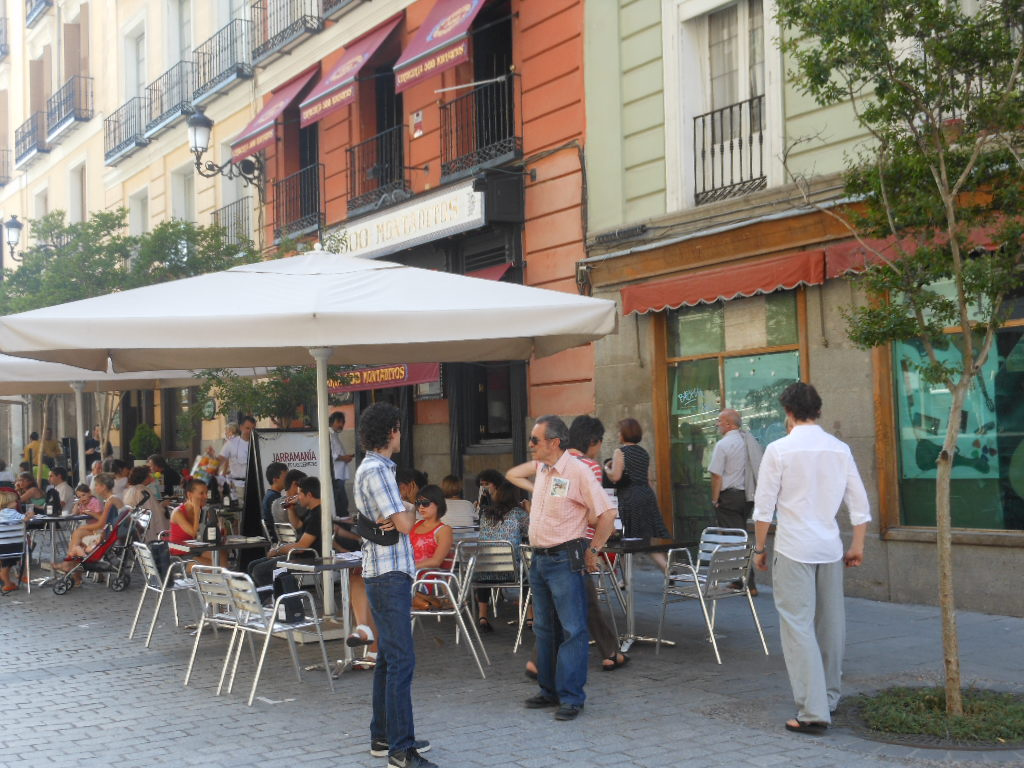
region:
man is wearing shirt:
[511, 445, 625, 554]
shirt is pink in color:
[520, 463, 623, 566]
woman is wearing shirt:
[337, 461, 420, 580]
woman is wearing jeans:
[357, 562, 449, 765]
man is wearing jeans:
[517, 542, 590, 708]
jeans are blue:
[512, 546, 598, 712]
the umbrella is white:
[325, 275, 384, 336]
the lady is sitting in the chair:
[477, 505, 525, 591]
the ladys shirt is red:
[173, 503, 199, 539]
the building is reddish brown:
[524, 37, 564, 92]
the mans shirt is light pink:
[536, 491, 568, 530]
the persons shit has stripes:
[572, 451, 610, 497]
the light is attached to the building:
[179, 101, 293, 201]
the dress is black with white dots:
[616, 449, 651, 508]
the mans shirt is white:
[793, 451, 829, 522]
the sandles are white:
[351, 620, 383, 681]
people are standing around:
[235, 326, 875, 751]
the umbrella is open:
[4, 43, 662, 439]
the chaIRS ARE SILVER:
[172, 557, 324, 679]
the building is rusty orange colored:
[216, 36, 571, 218]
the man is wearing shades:
[506, 370, 589, 459]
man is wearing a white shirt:
[697, 340, 882, 600]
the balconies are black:
[92, 26, 290, 192]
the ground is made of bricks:
[8, 671, 315, 758]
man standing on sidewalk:
[333, 401, 457, 765]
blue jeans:
[360, 569, 436, 750]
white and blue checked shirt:
[353, 449, 415, 582]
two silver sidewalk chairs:
[188, 554, 338, 711]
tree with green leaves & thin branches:
[833, 20, 1007, 744]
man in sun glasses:
[523, 407, 609, 730]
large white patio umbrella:
[11, 244, 619, 640]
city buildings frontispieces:
[9, 10, 1011, 595]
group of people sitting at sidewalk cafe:
[28, 415, 338, 567]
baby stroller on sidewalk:
[61, 489, 153, 588]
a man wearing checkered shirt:
[354, 397, 419, 609]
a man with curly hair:
[341, 398, 411, 462]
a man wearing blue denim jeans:
[343, 397, 427, 765]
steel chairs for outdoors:
[187, 553, 340, 725]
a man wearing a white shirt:
[738, 376, 876, 580]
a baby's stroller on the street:
[53, 487, 168, 605]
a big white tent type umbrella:
[9, 240, 665, 721]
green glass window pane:
[637, 259, 830, 534]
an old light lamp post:
[180, 92, 280, 245]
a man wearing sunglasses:
[524, 413, 582, 477]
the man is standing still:
[348, 408, 440, 762]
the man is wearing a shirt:
[754, 421, 875, 570]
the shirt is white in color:
[744, 424, 872, 577]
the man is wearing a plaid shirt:
[351, 456, 425, 578]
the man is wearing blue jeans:
[358, 566, 422, 748]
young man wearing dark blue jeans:
[353, 398, 436, 766]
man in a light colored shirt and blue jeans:
[522, 412, 615, 725]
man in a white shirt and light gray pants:
[751, 379, 872, 737]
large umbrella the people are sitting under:
[0, 240, 620, 642]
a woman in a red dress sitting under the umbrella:
[345, 481, 451, 674]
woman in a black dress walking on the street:
[603, 417, 677, 589]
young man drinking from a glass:
[247, 467, 323, 601]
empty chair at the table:
[657, 522, 771, 666]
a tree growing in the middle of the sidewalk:
[770, 1, 1023, 744]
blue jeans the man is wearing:
[528, 537, 592, 708]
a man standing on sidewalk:
[352, 393, 433, 763]